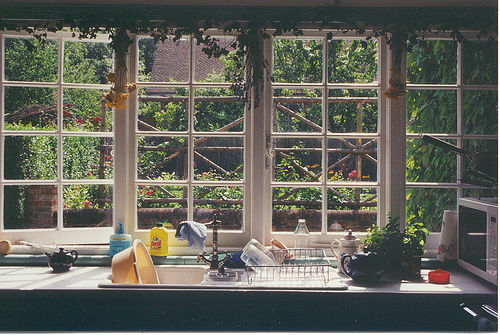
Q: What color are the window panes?
A: Clear.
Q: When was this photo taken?
A: During the day.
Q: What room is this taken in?
A: The kitchen.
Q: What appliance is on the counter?
A: A microwave.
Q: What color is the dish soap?
A: Yellow.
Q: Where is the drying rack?
A: Next to the sink.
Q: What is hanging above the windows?
A: Plants.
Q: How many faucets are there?
A: One.